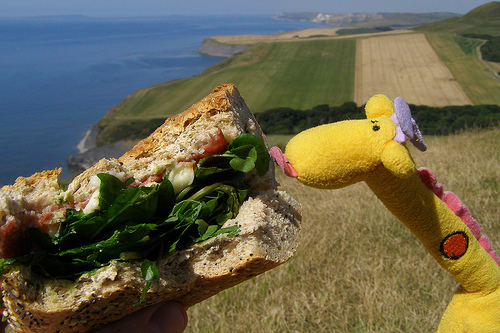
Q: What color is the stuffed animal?
A: Yellow, pink, and red.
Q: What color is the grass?
A: Green.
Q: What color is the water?
A: Blue.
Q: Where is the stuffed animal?
A: Next to the sandwich.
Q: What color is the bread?
A: Brown and white.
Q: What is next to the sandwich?
A: The stuffed animal.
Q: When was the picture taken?
A: Daytime.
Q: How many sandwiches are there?
A: One.